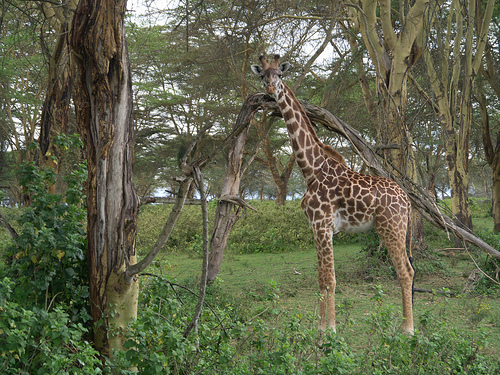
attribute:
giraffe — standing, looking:
[251, 59, 430, 319]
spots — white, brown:
[321, 180, 393, 222]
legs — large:
[312, 232, 425, 353]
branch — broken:
[183, 158, 220, 321]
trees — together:
[59, 6, 256, 343]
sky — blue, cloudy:
[113, 10, 455, 108]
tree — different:
[41, 8, 229, 311]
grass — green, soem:
[157, 227, 496, 309]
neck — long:
[275, 89, 320, 169]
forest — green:
[42, 25, 494, 199]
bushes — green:
[110, 186, 303, 251]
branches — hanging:
[232, 15, 340, 78]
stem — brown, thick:
[160, 179, 191, 255]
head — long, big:
[251, 52, 286, 93]